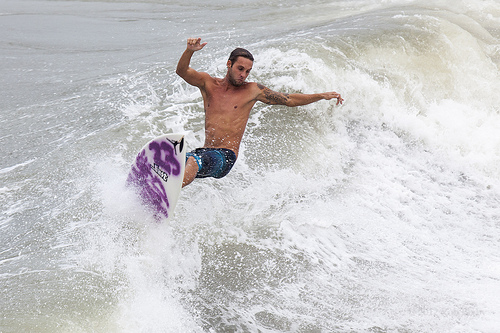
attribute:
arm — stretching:
[260, 80, 347, 111]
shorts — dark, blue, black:
[183, 142, 240, 182]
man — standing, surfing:
[162, 33, 346, 190]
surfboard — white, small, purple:
[125, 130, 188, 222]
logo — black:
[166, 136, 181, 154]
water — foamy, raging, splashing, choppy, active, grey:
[1, 2, 500, 332]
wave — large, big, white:
[103, 46, 500, 331]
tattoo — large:
[256, 83, 289, 106]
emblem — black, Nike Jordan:
[147, 158, 173, 185]